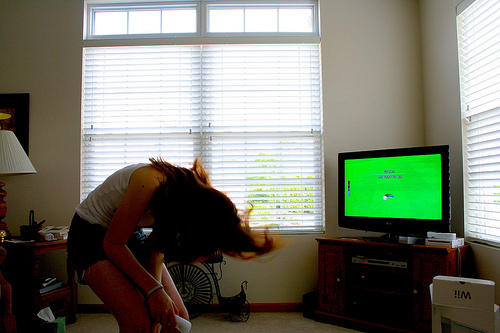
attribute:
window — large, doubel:
[83, 0, 320, 237]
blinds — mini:
[75, 39, 327, 239]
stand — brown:
[303, 237, 467, 332]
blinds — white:
[83, 6, 329, 234]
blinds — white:
[459, 5, 496, 243]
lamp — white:
[2, 127, 39, 238]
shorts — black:
[63, 206, 160, 283]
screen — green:
[335, 150, 445, 221]